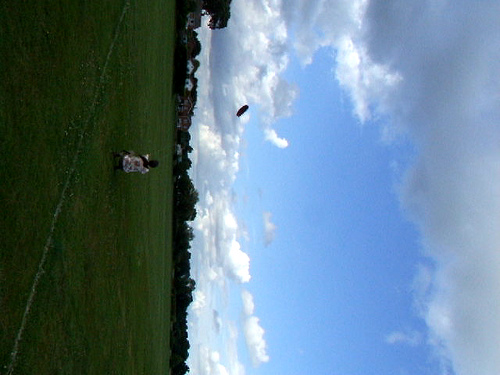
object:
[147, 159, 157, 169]
hair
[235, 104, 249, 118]
object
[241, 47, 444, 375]
blue sky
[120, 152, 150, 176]
shirt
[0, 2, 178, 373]
field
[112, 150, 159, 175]
person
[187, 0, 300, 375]
cloud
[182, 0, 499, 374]
sky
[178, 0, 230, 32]
tree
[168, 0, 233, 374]
foliage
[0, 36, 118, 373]
line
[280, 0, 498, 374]
clouds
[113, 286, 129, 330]
pale patch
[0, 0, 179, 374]
grass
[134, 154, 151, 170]
blemish